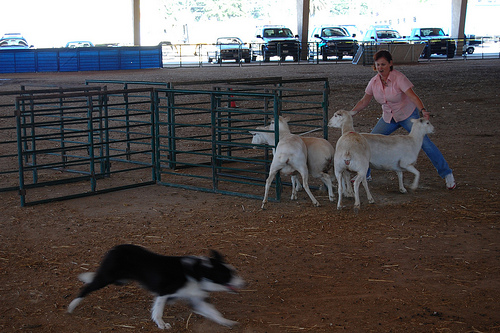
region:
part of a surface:
[388, 249, 418, 281]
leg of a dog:
[155, 304, 159, 317]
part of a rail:
[90, 126, 121, 164]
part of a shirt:
[382, 100, 396, 115]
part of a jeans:
[430, 138, 435, 156]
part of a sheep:
[286, 147, 312, 169]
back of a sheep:
[280, 152, 297, 171]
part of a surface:
[354, 212, 373, 293]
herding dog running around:
[57, 224, 285, 331]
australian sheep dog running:
[49, 220, 294, 331]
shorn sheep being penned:
[235, 88, 450, 206]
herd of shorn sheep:
[246, 108, 435, 209]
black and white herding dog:
[72, 224, 249, 331]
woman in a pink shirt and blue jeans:
[349, 47, 456, 198]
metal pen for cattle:
[12, 68, 322, 195]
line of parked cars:
[212, 20, 455, 62]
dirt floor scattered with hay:
[193, 204, 328, 251]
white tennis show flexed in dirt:
[440, 173, 457, 190]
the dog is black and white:
[83, 231, 229, 329]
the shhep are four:
[265, 106, 459, 205]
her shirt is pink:
[352, 66, 453, 146]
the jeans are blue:
[369, 106, 478, 183]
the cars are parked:
[210, 14, 467, 68]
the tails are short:
[264, 139, 384, 199]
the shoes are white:
[437, 173, 470, 198]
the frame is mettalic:
[75, 76, 251, 203]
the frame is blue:
[83, 70, 238, 204]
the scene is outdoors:
[16, 29, 487, 321]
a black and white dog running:
[62, 233, 243, 329]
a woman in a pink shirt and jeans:
[336, 47, 459, 189]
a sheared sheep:
[326, 105, 377, 210]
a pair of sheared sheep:
[244, 115, 336, 208]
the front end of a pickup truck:
[404, 23, 456, 58]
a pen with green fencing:
[2, 74, 337, 207]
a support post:
[296, 0, 311, 62]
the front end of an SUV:
[308, 25, 359, 61]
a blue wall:
[1, 45, 163, 70]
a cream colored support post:
[451, 0, 466, 56]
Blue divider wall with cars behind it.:
[4, 32, 169, 76]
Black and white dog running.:
[57, 232, 279, 327]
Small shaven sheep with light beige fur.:
[247, 105, 442, 214]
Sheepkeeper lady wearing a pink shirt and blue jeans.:
[338, 50, 460, 194]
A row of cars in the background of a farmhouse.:
[207, 15, 484, 66]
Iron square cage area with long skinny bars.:
[15, 59, 350, 197]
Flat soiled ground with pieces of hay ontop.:
[261, 208, 498, 331]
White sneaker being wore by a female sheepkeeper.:
[437, 164, 462, 190]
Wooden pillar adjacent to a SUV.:
[286, 0, 324, 59]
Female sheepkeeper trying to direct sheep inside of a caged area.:
[241, 42, 469, 228]